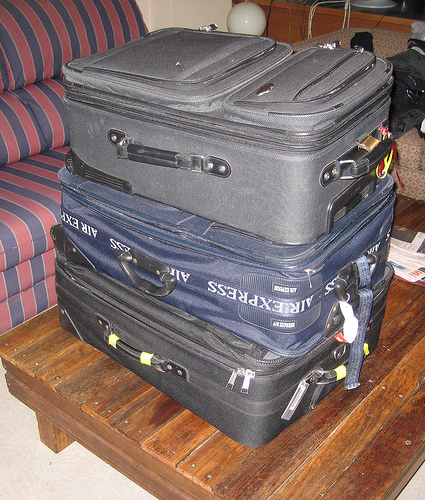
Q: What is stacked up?
A: Suitcases.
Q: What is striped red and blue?
A: Couch.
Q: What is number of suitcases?
A: Three.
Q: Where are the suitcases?
A: On table.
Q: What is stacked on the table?
A: Suitcases.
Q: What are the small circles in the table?
A: Nails.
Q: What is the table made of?
A: Wood.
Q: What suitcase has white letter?
A: The blue one.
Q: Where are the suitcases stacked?
A: On the table.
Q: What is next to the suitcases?
A: Newspaper.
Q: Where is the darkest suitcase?
A: Bottom.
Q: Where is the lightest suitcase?
A: Top.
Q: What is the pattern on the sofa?
A: Stripes.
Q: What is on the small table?
A: Stacked up luggages.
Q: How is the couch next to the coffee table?
A: Wide.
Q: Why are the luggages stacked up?
A: Not enough space to put them.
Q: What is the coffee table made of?
A: Wood.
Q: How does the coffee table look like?
A: Old and worn out.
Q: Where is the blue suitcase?
A: In the middle.